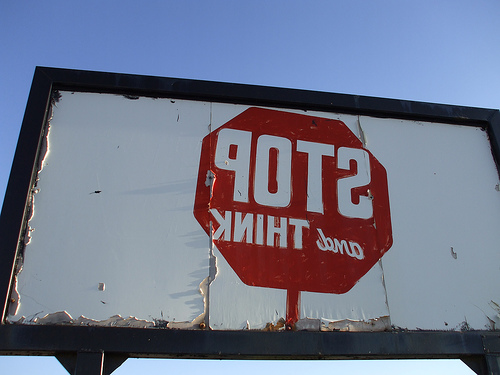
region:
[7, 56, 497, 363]
white sign with a black frame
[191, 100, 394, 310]
drawing of a red sign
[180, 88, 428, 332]
red octagon with white letters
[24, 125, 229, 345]
paper peeling off of a billboard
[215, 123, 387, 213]
the word "stop" displayed backwards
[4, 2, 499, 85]
blue sky above the sky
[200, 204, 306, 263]
the word "think" shown backwards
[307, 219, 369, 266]
the word "and" backwards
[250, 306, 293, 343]
brown spot on the damaged sign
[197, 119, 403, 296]
the words "stop and think" displayed backwards on the red sign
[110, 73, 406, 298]
lettering backwards on sign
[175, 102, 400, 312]
red and white sign on a black and white sign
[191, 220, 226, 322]
curled edges of paper panels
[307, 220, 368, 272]
white scripted writing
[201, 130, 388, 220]
white lettering in capital letters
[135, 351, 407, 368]
sky showing under sign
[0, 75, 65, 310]
torn paper along side frame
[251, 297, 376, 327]
puckering above ripped paper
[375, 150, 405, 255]
smooth edge of red sign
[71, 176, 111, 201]
black mark on white paper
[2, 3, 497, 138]
Clear blue sky.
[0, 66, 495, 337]
Tall billboard sign.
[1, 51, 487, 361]
Black frame to the billboard.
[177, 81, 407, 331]
Backwards red stop sign on the billboard.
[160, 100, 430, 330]
STOP and THINK written backwards on the billboard.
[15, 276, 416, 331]
Parts of the billboard ripping away.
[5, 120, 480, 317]
White base of the billboard.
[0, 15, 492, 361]
Nobody pictured within the photo.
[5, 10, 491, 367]
Photo taken during the day.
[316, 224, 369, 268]
"and" written in cursive and backwards.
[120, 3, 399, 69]
a clear blue sky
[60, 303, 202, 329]
peeling paint on the sign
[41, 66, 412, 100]
a black frame around a bill board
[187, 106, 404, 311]
a red stop sign on a bill board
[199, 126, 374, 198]
white letters on a red sign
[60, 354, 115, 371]
a wooden post supporting a sign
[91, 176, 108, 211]
dirt on the bill board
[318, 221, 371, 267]
cursive writing on the sign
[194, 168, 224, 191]
a small hole in the sign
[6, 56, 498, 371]
a large bill board with a stop sign on it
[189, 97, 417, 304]
backwards stop sign on board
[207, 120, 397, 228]
backwards word in white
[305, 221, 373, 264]
word written in cursive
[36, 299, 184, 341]
torn edges of sign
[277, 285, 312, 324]
red pole on painted sign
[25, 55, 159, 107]
black wood frame of sign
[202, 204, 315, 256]
tall capital letters in white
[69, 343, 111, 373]
pole holding sign up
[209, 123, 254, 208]
letter P on stop sign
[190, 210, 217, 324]
worn line on sign